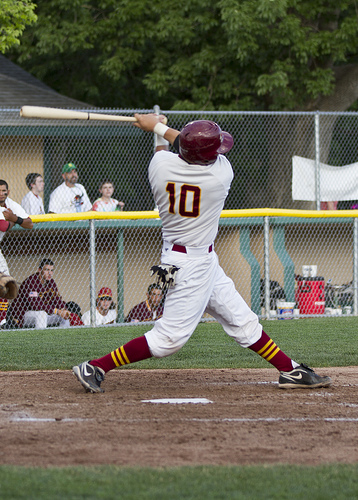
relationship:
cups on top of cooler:
[297, 262, 320, 276] [296, 276, 326, 314]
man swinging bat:
[71, 112, 330, 392] [19, 103, 168, 126]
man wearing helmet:
[71, 112, 330, 392] [177, 118, 233, 166]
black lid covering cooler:
[298, 277, 322, 281] [296, 276, 326, 314]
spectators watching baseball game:
[0, 179, 34, 231] [14, 63, 350, 414]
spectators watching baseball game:
[20, 169, 47, 216] [14, 63, 350, 414]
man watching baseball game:
[47, 161, 93, 213] [14, 63, 350, 414]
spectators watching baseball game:
[86, 179, 124, 212] [14, 63, 350, 414]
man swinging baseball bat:
[11, 98, 335, 392] [16, 102, 167, 127]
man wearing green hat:
[47, 161, 93, 213] [60, 162, 77, 172]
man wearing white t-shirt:
[47, 161, 93, 213] [47, 183, 91, 215]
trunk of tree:
[245, 85, 351, 200] [146, 5, 300, 91]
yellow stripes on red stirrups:
[109, 344, 129, 365] [96, 334, 153, 369]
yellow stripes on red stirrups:
[109, 344, 129, 365] [248, 334, 293, 372]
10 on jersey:
[164, 180, 201, 217] [146, 150, 234, 249]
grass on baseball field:
[4, 466, 356, 495] [0, 316, 357, 498]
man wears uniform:
[71, 112, 330, 392] [88, 148, 300, 374]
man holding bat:
[71, 112, 330, 392] [19, 104, 138, 123]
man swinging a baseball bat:
[71, 112, 330, 392] [20, 104, 168, 126]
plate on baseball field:
[137, 388, 212, 409] [1, 310, 352, 405]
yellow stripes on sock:
[109, 349, 122, 367] [88, 335, 151, 372]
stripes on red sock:
[257, 337, 282, 361] [248, 329, 294, 371]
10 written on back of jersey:
[164, 180, 201, 217] [146, 150, 234, 249]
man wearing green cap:
[47, 161, 93, 213] [61, 162, 78, 170]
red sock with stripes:
[248, 334, 296, 376] [265, 345, 280, 360]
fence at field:
[2, 108, 357, 261] [6, 306, 350, 498]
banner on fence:
[289, 155, 356, 203] [1, 103, 356, 332]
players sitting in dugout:
[0, 254, 167, 323] [3, 223, 352, 303]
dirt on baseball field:
[8, 392, 113, 448] [4, 110, 353, 496]